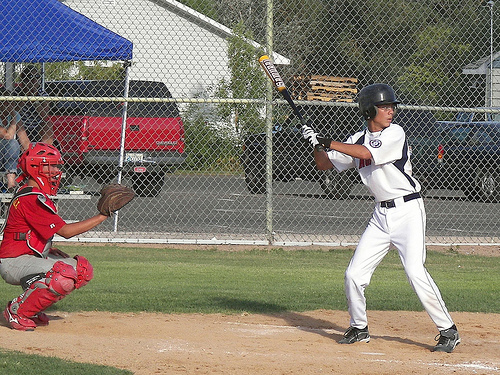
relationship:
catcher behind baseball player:
[0, 77, 140, 369] [298, 82, 462, 354]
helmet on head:
[358, 82, 402, 122] [361, 89, 396, 129]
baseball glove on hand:
[96, 184, 137, 217] [96, 179, 134, 220]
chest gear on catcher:
[0, 183, 59, 247] [0, 139, 120, 333]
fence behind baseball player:
[1, 2, 498, 244] [298, 82, 462, 354]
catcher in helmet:
[0, 141, 138, 333] [14, 142, 64, 197]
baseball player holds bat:
[301, 82, 461, 352] [257, 52, 324, 152]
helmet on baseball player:
[357, 81, 398, 124] [298, 82, 462, 354]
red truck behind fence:
[46, 76, 189, 196] [1, 2, 498, 244]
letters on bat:
[261, 59, 286, 84] [257, 53, 325, 153]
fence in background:
[1, 2, 498, 244] [15, 8, 265, 137]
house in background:
[0, 1, 292, 148] [6, 8, 271, 151]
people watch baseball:
[0, 63, 56, 192] [0, 81, 463, 353]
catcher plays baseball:
[0, 141, 138, 333] [8, 49, 468, 367]